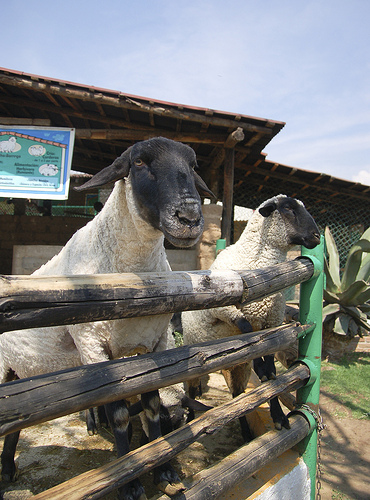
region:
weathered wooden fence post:
[241, 251, 311, 301]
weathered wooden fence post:
[9, 321, 297, 435]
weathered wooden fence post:
[26, 365, 310, 498]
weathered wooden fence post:
[146, 413, 310, 498]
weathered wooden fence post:
[7, 265, 242, 328]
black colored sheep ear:
[72, 156, 129, 196]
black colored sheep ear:
[192, 166, 216, 200]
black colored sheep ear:
[257, 197, 276, 218]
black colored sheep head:
[127, 133, 205, 249]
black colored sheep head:
[278, 193, 326, 254]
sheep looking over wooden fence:
[54, 137, 332, 494]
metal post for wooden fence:
[286, 225, 333, 498]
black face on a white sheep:
[69, 137, 218, 251]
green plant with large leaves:
[319, 218, 367, 353]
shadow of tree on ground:
[323, 406, 368, 493]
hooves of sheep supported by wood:
[254, 366, 301, 432]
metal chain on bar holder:
[293, 398, 332, 495]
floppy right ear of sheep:
[60, 138, 128, 191]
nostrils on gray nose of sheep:
[172, 203, 200, 225]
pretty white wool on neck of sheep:
[74, 232, 124, 264]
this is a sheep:
[14, 100, 233, 476]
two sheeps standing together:
[28, 113, 338, 494]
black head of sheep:
[103, 126, 227, 261]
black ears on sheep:
[63, 153, 222, 198]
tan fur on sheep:
[14, 195, 182, 376]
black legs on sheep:
[96, 390, 183, 465]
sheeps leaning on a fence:
[34, 129, 342, 487]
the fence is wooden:
[21, 226, 334, 498]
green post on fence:
[277, 214, 341, 480]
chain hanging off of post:
[289, 384, 348, 498]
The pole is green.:
[311, 243, 328, 397]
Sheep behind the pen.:
[63, 163, 319, 347]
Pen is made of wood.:
[57, 295, 299, 442]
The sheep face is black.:
[145, 147, 217, 251]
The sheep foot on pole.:
[151, 464, 179, 499]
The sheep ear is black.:
[64, 143, 140, 192]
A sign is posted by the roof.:
[16, 108, 98, 204]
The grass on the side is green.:
[330, 357, 361, 390]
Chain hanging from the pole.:
[303, 407, 336, 481]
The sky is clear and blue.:
[151, 26, 334, 117]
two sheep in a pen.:
[2, 137, 322, 475]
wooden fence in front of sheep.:
[0, 261, 321, 496]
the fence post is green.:
[296, 228, 316, 496]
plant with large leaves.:
[318, 222, 365, 359]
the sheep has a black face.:
[80, 137, 206, 235]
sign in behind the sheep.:
[1, 124, 69, 198]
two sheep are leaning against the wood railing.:
[5, 136, 317, 421]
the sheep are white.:
[7, 138, 322, 422]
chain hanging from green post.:
[302, 396, 328, 498]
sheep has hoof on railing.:
[153, 465, 187, 495]